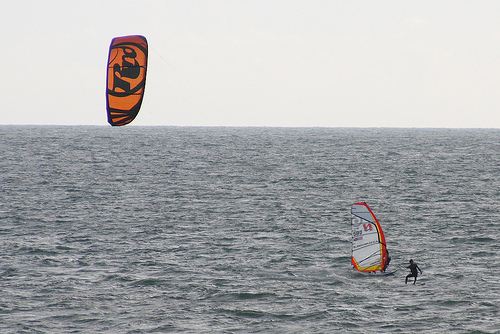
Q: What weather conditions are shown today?
A: It is overcast.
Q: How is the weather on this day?
A: It is overcast.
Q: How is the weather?
A: It is overcast.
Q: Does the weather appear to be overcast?
A: Yes, it is overcast.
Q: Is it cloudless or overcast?
A: It is overcast.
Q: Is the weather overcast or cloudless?
A: It is overcast.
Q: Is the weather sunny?
A: No, it is overcast.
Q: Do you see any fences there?
A: No, there are no fences.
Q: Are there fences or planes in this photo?
A: No, there are no fences or planes.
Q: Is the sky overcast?
A: Yes, the sky is overcast.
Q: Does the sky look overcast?
A: Yes, the sky is overcast.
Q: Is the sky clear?
A: No, the sky is overcast.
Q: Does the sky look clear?
A: No, the sky is overcast.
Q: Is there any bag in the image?
A: No, there are no bags.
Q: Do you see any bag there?
A: No, there are no bags.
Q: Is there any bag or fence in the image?
A: No, there are no bags or fences.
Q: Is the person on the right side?
A: Yes, the person is on the right of the image.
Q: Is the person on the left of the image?
A: No, the person is on the right of the image.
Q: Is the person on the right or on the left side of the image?
A: The person is on the right of the image.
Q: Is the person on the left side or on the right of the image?
A: The person is on the right of the image.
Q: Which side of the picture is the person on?
A: The person is on the right of the image.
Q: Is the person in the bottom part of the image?
A: Yes, the person is in the bottom of the image.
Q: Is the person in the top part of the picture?
A: No, the person is in the bottom of the image.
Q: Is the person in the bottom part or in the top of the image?
A: The person is in the bottom of the image.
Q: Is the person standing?
A: Yes, the person is standing.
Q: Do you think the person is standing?
A: Yes, the person is standing.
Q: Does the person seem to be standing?
A: Yes, the person is standing.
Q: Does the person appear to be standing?
A: Yes, the person is standing.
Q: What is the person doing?
A: The person is standing.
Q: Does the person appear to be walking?
A: No, the person is standing.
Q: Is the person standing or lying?
A: The person is standing.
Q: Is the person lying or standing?
A: The person is standing.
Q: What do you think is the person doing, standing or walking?
A: The person is standing.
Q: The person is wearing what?
A: The person is wearing a wetsuit.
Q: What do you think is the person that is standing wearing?
A: The person is wearing a wetsuit.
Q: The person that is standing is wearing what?
A: The person is wearing a wetsuit.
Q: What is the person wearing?
A: The person is wearing a wetsuit.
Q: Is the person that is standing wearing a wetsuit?
A: Yes, the person is wearing a wetsuit.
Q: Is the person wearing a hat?
A: No, the person is wearing a wetsuit.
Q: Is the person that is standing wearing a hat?
A: No, the person is wearing a wetsuit.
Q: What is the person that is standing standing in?
A: The person is standing in the water.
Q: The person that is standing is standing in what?
A: The person is standing in the water.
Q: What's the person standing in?
A: The person is standing in the water.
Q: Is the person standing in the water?
A: Yes, the person is standing in the water.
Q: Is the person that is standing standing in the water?
A: Yes, the person is standing in the water.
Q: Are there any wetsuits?
A: Yes, there is a wetsuit.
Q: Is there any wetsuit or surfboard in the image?
A: Yes, there is a wetsuit.